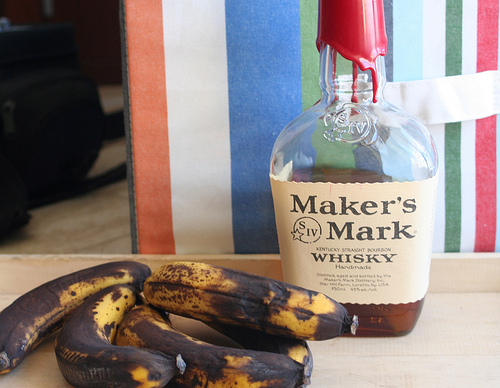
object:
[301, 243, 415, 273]
word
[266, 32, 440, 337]
bottle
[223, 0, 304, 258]
stripe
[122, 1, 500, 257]
wall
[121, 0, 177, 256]
stripe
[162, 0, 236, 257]
stripe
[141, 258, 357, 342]
bananas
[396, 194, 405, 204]
apostrophe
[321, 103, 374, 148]
circle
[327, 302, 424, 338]
liquid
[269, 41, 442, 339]
glass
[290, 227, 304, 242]
star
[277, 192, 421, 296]
label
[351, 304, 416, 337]
whisky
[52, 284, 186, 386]
banana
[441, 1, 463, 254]
stripe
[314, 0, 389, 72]
top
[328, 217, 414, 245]
mark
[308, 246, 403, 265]
whisky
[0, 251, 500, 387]
table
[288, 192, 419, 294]
text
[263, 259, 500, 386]
counter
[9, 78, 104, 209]
bag